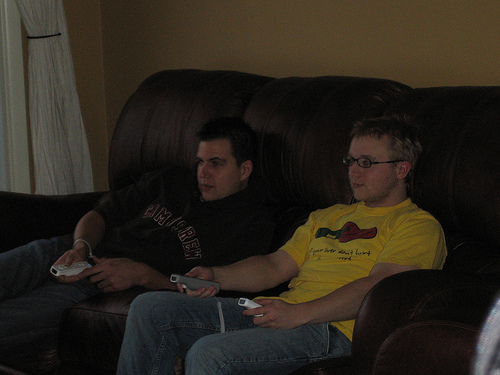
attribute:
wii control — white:
[44, 261, 94, 278]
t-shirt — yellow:
[280, 201, 452, 345]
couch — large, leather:
[155, 71, 499, 129]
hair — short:
[349, 117, 421, 161]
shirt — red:
[90, 183, 285, 293]